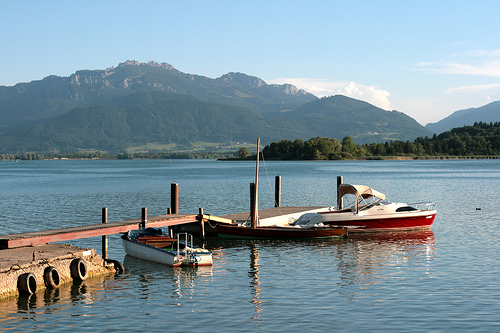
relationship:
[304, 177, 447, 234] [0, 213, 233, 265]
boat at dock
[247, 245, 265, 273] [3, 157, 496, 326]
reflection in water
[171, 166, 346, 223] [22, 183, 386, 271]
post on pier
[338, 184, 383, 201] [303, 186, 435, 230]
covering on boat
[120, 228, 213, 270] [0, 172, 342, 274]
boat mocked pier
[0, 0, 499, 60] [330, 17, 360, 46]
sky seen part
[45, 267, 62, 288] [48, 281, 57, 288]
wheel seen part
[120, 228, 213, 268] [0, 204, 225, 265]
boat near dock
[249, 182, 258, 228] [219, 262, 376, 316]
post in water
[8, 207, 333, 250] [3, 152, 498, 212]
boardwalk over water